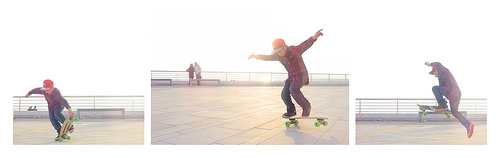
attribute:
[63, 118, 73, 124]
wheel — green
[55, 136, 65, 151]
wheel — green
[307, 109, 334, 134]
wheel — green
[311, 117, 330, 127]
wheel — green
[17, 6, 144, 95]
sky — white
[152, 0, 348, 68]
sky — white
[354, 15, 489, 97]
sky — white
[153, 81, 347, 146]
floor — lit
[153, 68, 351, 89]
gate — metal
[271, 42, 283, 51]
hat — red, grey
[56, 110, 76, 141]
skateboard — black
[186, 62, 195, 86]
person — watching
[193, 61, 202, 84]
person — watching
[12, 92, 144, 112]
gate — metal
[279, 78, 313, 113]
jeans — blue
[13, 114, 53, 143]
line — yellow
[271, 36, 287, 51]
cap — red